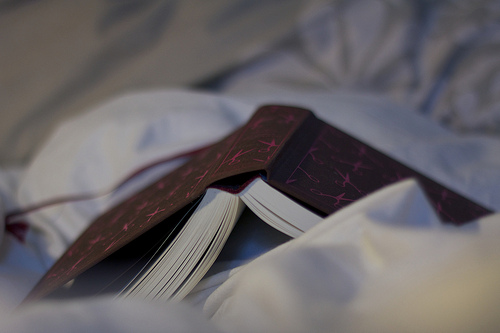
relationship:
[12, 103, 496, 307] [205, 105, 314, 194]
book has a spine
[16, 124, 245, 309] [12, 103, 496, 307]
front cover of book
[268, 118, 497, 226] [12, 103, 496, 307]
back cover of book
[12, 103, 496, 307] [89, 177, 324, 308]
book has pages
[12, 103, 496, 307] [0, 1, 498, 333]
book on bed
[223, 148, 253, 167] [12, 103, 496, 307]
scissors are on book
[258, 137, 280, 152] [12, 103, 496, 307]
scissors are on book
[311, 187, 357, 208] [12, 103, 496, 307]
scissors are on book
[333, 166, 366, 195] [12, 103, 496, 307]
scissors are on book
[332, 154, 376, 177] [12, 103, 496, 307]
scissors are on book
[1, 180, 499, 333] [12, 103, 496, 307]
sheet in front of book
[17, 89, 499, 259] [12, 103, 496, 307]
pillow behind book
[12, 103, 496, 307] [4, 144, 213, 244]
book has a bookmark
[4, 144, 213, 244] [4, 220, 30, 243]
bookmark has an end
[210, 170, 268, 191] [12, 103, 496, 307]
gap in book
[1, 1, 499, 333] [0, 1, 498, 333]
fabric on bed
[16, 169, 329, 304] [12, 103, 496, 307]
top of book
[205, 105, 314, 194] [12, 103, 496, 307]
spine of book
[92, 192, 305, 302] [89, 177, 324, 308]
gaps are in pages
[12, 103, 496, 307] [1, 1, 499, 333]
book on fabric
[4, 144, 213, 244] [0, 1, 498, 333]
bookmark on bed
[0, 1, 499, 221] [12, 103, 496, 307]
sheet behind book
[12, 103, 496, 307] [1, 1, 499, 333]
book on sheet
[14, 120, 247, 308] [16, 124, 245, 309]
pattern on front cover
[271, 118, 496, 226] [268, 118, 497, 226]
pattern on back cover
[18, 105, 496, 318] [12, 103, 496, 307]
pattern on book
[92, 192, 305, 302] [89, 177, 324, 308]
gaps are between pages